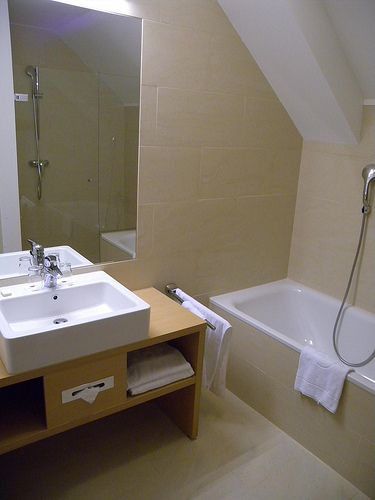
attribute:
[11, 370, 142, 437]
tissue — holder, cabinet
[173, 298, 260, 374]
towel — white, hanging, rack, side, folded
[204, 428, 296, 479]
floor — white, light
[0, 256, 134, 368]
sink — basin, bath, bathroom, white, silver, empt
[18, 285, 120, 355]
glass — cup, drinking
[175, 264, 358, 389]
tub — bath, white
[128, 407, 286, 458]
mat — white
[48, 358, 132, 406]
dispenser — silver, tissue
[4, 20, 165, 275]
mirror — mounted, large, clean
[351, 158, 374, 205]
shower — nozzle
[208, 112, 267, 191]
tile — beige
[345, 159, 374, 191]
head — shower, metal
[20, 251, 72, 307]
faucet — silver, off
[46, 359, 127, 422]
box — tissue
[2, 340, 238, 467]
cabinet — wooden